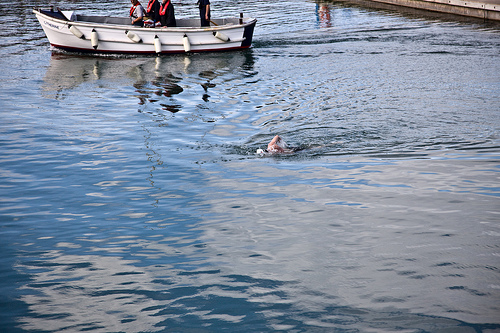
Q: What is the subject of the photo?
A: Swimmer.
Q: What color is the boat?
A: White.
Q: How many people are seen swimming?
A: One.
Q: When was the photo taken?
A: Daytime.